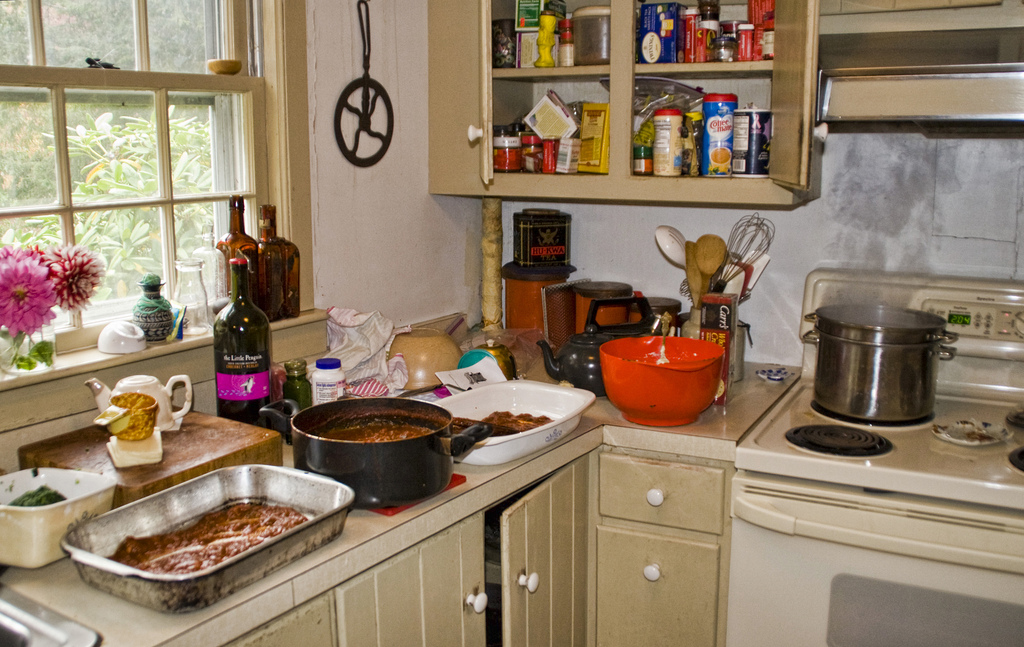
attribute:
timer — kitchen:
[81, 318, 155, 354]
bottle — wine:
[200, 257, 276, 429]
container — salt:
[725, 104, 771, 188]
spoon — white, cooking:
[645, 219, 684, 273]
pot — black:
[526, 317, 613, 393]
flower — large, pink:
[1, 254, 55, 340]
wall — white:
[294, 8, 465, 323]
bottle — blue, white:
[305, 349, 343, 403]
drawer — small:
[596, 451, 720, 525]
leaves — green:
[16, 104, 197, 291]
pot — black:
[288, 393, 462, 511]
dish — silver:
[57, 459, 358, 612]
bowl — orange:
[597, 332, 730, 432]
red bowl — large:
[592, 330, 738, 438]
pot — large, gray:
[807, 302, 960, 430]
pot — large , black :
[272, 399, 488, 511]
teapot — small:
[498, 265, 686, 426]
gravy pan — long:
[46, 382, 423, 599]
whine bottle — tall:
[180, 239, 315, 449]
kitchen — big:
[9, 4, 1018, 616]